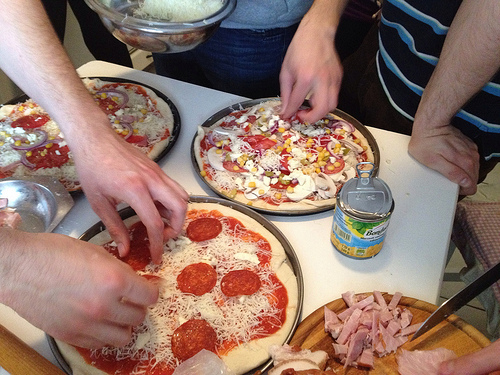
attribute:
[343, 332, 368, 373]
ham — cut, small, chopped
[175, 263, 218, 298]
pepperoni — single, placed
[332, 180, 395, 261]
can — full, silver, aluminum, tin, open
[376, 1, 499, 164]
shirt — striped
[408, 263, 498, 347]
knife — sharp, chopping